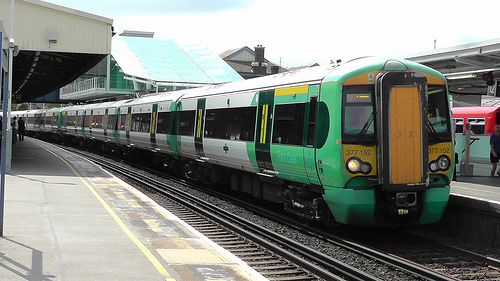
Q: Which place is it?
A: It is a pavement.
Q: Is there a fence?
A: No, there are no fences.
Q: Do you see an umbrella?
A: No, there are no umbrellas.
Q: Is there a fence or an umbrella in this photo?
A: No, there are no umbrellas or fences.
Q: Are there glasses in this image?
A: No, there are no glasses.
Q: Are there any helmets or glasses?
A: No, there are no glasses or helmets.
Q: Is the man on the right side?
A: Yes, the man is on the right of the image.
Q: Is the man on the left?
A: No, the man is on the right of the image.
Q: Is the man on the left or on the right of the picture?
A: The man is on the right of the image.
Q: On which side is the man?
A: The man is on the right of the image.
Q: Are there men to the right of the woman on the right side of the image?
A: Yes, there is a man to the right of the woman.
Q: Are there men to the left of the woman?
A: No, the man is to the right of the woman.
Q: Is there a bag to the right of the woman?
A: No, there is a man to the right of the woman.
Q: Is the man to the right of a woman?
A: Yes, the man is to the right of a woman.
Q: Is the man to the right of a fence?
A: No, the man is to the right of a woman.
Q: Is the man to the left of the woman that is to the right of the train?
A: No, the man is to the right of the woman.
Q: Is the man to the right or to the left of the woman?
A: The man is to the right of the woman.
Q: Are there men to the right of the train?
A: Yes, there is a man to the right of the train.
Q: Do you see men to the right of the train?
A: Yes, there is a man to the right of the train.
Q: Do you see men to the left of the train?
A: No, the man is to the right of the train.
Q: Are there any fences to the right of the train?
A: No, there is a man to the right of the train.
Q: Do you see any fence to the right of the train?
A: No, there is a man to the right of the train.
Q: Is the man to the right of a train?
A: Yes, the man is to the right of a train.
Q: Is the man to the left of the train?
A: No, the man is to the right of the train.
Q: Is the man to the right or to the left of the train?
A: The man is to the right of the train.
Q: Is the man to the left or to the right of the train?
A: The man is to the right of the train.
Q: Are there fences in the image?
A: No, there are no fences.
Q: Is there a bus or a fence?
A: No, there are no fences or buses.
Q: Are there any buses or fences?
A: No, there are no fences or buses.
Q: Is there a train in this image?
A: Yes, there is a train.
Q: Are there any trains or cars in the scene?
A: Yes, there is a train.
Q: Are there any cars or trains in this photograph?
A: Yes, there is a train.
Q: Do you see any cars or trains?
A: Yes, there is a train.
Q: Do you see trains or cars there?
A: Yes, there is a train.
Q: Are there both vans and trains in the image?
A: No, there is a train but no vans.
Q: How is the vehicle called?
A: The vehicle is a train.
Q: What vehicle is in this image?
A: The vehicle is a train.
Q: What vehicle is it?
A: The vehicle is a train.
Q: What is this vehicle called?
A: This is a train.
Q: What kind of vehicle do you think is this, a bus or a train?
A: This is a train.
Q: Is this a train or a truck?
A: This is a train.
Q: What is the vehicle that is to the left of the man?
A: The vehicle is a train.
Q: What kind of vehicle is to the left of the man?
A: The vehicle is a train.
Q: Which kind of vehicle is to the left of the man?
A: The vehicle is a train.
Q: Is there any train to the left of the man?
A: Yes, there is a train to the left of the man.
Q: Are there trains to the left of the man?
A: Yes, there is a train to the left of the man.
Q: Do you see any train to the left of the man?
A: Yes, there is a train to the left of the man.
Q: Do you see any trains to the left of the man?
A: Yes, there is a train to the left of the man.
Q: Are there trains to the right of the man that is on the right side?
A: No, the train is to the left of the man.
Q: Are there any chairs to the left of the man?
A: No, there is a train to the left of the man.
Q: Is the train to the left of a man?
A: Yes, the train is to the left of a man.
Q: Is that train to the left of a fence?
A: No, the train is to the left of a man.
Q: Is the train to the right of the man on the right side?
A: No, the train is to the left of the man.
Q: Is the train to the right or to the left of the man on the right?
A: The train is to the left of the man.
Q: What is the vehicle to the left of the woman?
A: The vehicle is a train.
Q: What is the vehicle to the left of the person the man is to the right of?
A: The vehicle is a train.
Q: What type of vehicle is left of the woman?
A: The vehicle is a train.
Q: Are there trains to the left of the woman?
A: Yes, there is a train to the left of the woman.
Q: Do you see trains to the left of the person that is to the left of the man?
A: Yes, there is a train to the left of the woman.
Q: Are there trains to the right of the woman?
A: No, the train is to the left of the woman.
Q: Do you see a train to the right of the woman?
A: No, the train is to the left of the woman.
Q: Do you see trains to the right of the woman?
A: No, the train is to the left of the woman.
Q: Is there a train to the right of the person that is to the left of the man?
A: No, the train is to the left of the woman.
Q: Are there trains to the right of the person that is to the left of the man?
A: No, the train is to the left of the woman.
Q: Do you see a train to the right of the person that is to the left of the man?
A: No, the train is to the left of the woman.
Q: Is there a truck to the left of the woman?
A: No, there is a train to the left of the woman.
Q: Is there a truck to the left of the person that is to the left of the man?
A: No, there is a train to the left of the woman.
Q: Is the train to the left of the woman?
A: Yes, the train is to the left of the woman.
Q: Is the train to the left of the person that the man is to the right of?
A: Yes, the train is to the left of the woman.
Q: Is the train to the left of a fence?
A: No, the train is to the left of the woman.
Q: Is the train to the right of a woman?
A: No, the train is to the left of a woman.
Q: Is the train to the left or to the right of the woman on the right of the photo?
A: The train is to the left of the woman.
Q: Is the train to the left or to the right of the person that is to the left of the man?
A: The train is to the left of the woman.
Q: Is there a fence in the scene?
A: No, there are no fences.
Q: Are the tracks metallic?
A: Yes, the tracks are metallic.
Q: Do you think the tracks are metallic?
A: Yes, the tracks are metallic.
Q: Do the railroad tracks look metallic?
A: Yes, the railroad tracks are metallic.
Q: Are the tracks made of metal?
A: Yes, the tracks are made of metal.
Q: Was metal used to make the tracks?
A: Yes, the tracks are made of metal.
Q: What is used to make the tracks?
A: The tracks are made of metal.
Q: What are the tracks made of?
A: The tracks are made of metal.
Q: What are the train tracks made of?
A: The tracks are made of metal.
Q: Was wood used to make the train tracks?
A: No, the train tracks are made of metal.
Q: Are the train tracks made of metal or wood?
A: The train tracks are made of metal.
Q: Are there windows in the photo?
A: Yes, there is a window.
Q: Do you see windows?
A: Yes, there is a window.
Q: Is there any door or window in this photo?
A: Yes, there is a window.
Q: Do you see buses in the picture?
A: No, there are no buses.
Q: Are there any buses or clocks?
A: No, there are no buses or clocks.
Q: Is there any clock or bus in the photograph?
A: No, there are no buses or clocks.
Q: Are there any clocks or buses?
A: No, there are no buses or clocks.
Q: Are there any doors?
A: Yes, there is a door.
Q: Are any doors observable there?
A: Yes, there is a door.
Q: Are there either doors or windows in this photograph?
A: Yes, there is a door.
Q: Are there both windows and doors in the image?
A: Yes, there are both a door and a window.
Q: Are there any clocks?
A: No, there are no clocks.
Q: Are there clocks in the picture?
A: No, there are no clocks.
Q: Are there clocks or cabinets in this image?
A: No, there are no clocks or cabinets.